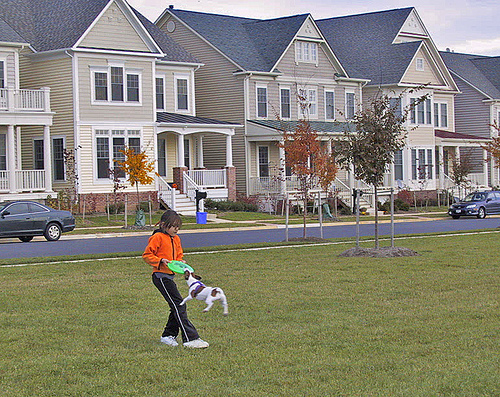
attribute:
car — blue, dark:
[0, 199, 74, 247]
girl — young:
[144, 210, 210, 351]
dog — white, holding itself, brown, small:
[178, 269, 230, 318]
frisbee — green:
[165, 258, 194, 279]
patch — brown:
[186, 283, 206, 299]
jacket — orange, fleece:
[143, 231, 186, 281]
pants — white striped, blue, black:
[152, 273, 200, 342]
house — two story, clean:
[2, 2, 239, 220]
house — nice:
[152, 7, 376, 217]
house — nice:
[304, 7, 492, 217]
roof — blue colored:
[317, 9, 460, 95]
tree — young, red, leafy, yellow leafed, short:
[124, 142, 155, 230]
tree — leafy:
[276, 111, 325, 244]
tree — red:
[310, 146, 343, 240]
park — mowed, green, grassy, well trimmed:
[3, 216, 500, 393]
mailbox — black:
[192, 189, 208, 225]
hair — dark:
[158, 208, 182, 234]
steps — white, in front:
[158, 189, 198, 217]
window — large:
[128, 132, 143, 185]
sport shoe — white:
[181, 336, 209, 350]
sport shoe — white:
[159, 334, 179, 350]